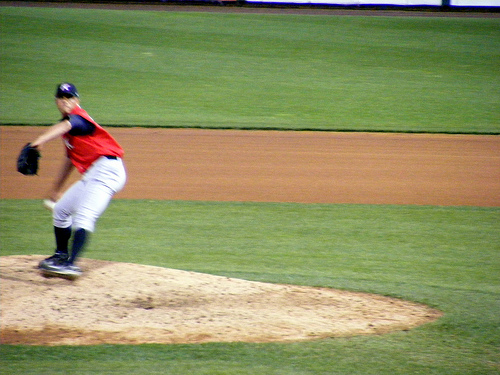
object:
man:
[16, 82, 127, 280]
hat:
[54, 81, 80, 98]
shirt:
[58, 108, 124, 173]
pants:
[52, 155, 127, 231]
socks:
[53, 226, 93, 266]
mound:
[0, 254, 440, 344]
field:
[119, 9, 500, 373]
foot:
[42, 260, 82, 280]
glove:
[16, 142, 42, 177]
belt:
[104, 155, 117, 160]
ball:
[42, 197, 56, 211]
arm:
[51, 156, 77, 194]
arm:
[32, 112, 81, 147]